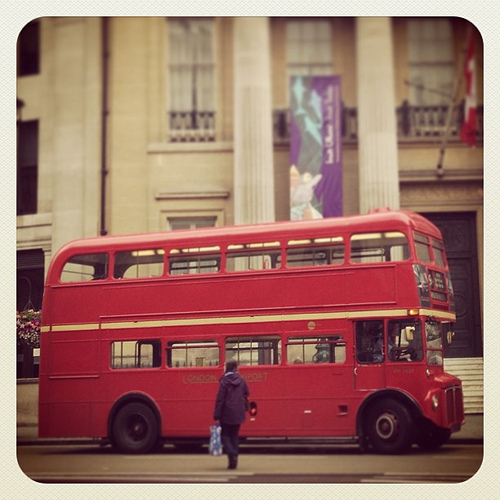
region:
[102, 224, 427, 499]
The bus is red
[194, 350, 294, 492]
The person is standing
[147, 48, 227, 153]
The window is on the building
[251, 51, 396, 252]
A flag is hanging from the building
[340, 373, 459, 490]
The wheel is round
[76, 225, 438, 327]
The bus has windows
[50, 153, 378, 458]
The bus is parked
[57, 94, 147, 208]
The building is light in color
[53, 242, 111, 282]
the window of a bus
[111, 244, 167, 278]
the window of a bus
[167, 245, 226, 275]
the window of a bus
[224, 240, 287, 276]
the window of a bus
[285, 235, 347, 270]
the window of a bus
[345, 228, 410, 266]
the window of a bus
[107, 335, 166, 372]
the window of a bus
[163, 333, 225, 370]
the window of a bus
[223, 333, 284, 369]
the window of a bus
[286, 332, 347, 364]
the window of a bus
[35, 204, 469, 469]
red double decker bus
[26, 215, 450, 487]
red double decker bus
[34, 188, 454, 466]
red double decker bus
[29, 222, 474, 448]
red double decker bus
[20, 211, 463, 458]
red double decker bus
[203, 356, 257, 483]
girl is wearing a jacket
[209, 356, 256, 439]
girl is wearing a jacket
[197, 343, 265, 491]
the woman is holding a bag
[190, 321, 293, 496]
she is holding a shopping bag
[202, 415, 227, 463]
this is a blue bag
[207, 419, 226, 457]
a blue shopping bag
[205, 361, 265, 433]
she is wearing a large coat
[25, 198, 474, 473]
this is a double decker bus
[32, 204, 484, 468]
the bus is red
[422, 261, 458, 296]
a black sign on the bus front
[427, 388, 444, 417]
this is a headlight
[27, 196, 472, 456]
A bus in the foreground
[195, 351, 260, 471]
A person in the foreground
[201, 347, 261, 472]
Person is holding a blue bag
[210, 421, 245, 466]
Person is wearing jeans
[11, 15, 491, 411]
A building in the background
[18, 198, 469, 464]
The bus is a double decker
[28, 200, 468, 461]
A side view of a bus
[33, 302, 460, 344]
A long yellow line on the bus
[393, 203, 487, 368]
A dark brown door